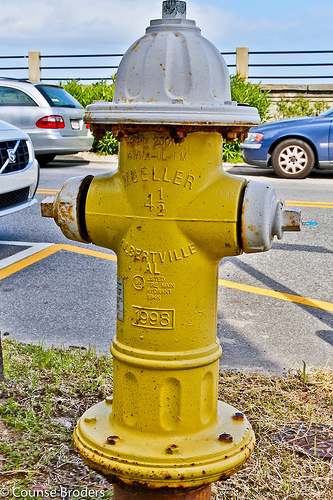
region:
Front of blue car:
[241, 93, 330, 168]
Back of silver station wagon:
[0, 63, 96, 162]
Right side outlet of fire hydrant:
[240, 176, 299, 255]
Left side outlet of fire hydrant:
[36, 168, 98, 251]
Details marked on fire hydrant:
[120, 156, 201, 335]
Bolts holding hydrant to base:
[102, 427, 243, 462]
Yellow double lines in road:
[283, 194, 331, 211]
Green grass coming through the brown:
[4, 342, 105, 394]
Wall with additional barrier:
[244, 47, 322, 113]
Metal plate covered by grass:
[271, 415, 332, 466]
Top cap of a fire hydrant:
[72, 0, 275, 127]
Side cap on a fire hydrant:
[231, 172, 311, 259]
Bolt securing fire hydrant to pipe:
[105, 430, 122, 452]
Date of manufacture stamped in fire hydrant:
[128, 304, 177, 337]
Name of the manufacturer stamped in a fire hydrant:
[114, 165, 204, 273]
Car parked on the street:
[242, 95, 332, 178]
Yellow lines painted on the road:
[244, 272, 318, 322]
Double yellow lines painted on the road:
[298, 188, 323, 208]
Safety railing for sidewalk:
[259, 48, 322, 80]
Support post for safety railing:
[234, 38, 255, 84]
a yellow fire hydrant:
[35, 0, 309, 498]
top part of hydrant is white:
[76, 0, 273, 128]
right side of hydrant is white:
[238, 171, 311, 255]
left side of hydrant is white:
[34, 168, 102, 251]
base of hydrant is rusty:
[52, 395, 269, 496]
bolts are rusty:
[212, 397, 246, 451]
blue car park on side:
[235, 101, 329, 170]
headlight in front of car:
[238, 129, 255, 144]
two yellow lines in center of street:
[292, 193, 329, 213]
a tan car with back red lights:
[1, 70, 96, 165]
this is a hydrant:
[71, 15, 268, 496]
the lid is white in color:
[143, 38, 202, 92]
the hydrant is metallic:
[132, 298, 214, 438]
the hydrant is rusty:
[240, 188, 296, 251]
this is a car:
[265, 118, 326, 172]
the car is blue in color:
[300, 118, 325, 140]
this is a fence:
[275, 45, 296, 75]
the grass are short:
[17, 349, 88, 405]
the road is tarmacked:
[43, 264, 91, 311]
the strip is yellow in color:
[252, 282, 283, 307]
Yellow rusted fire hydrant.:
[26, 5, 304, 496]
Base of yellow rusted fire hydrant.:
[63, 399, 256, 498]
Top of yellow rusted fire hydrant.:
[68, 2, 270, 127]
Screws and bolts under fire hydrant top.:
[93, 127, 251, 147]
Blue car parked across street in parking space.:
[239, 103, 332, 178]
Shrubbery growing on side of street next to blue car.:
[227, 74, 323, 161]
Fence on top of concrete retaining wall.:
[231, 45, 331, 85]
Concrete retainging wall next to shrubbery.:
[239, 80, 330, 115]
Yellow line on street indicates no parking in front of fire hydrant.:
[221, 275, 331, 335]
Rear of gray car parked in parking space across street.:
[4, 75, 98, 170]